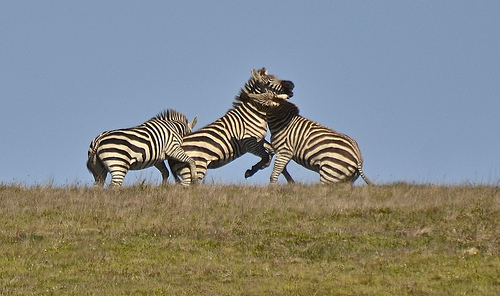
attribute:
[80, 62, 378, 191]
zebras — fighting, three, playing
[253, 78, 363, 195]
zebra — black, white, striped, jumping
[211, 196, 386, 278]
grass — light green, brow, tall, green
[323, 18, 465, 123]
sky — blue, clear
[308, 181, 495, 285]
hill — grassy, small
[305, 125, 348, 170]
stripes — black, white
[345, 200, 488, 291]
area — grass